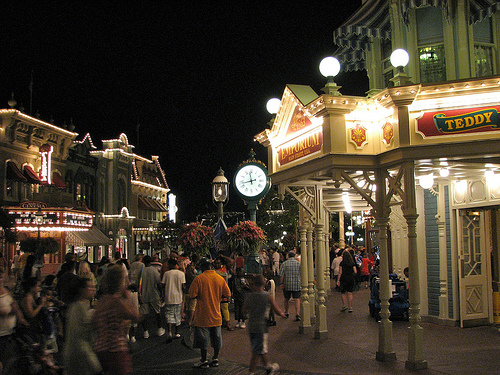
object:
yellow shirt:
[188, 270, 231, 329]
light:
[318, 57, 341, 78]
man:
[138, 256, 163, 338]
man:
[279, 250, 302, 320]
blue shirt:
[280, 258, 301, 291]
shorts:
[283, 290, 301, 299]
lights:
[390, 49, 410, 68]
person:
[93, 265, 137, 371]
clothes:
[89, 293, 140, 353]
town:
[1, 4, 498, 332]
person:
[160, 259, 186, 338]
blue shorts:
[192, 326, 223, 350]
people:
[244, 274, 288, 374]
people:
[22, 277, 51, 363]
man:
[188, 257, 232, 368]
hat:
[198, 257, 211, 267]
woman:
[337, 251, 358, 312]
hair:
[342, 251, 353, 266]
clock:
[234, 165, 267, 197]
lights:
[271, 119, 322, 150]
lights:
[347, 98, 395, 124]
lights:
[408, 90, 500, 112]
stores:
[256, 50, 497, 351]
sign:
[432, 109, 498, 135]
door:
[456, 206, 498, 329]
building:
[0, 110, 174, 368]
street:
[129, 304, 388, 373]